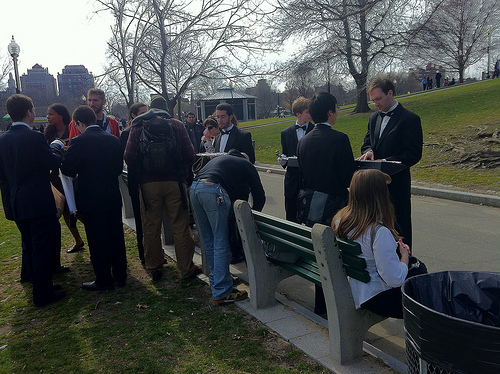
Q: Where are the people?
A: In a park.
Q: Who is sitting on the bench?
A: A woman.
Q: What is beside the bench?
A: A trash can.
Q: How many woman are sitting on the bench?
A: 1.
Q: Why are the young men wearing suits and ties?
A: For a formal event.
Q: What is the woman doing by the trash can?
A: Sitting on a bench.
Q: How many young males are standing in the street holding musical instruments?
A: 3.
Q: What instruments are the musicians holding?
A: Keyboards.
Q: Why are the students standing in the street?
A: Waiting for a competition.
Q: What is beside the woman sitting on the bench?
A: Trash can.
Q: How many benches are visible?
A: 1.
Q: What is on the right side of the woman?
A: Trash can.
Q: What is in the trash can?
A: Bag.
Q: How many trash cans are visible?
A: 1.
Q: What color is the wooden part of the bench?
A: Green.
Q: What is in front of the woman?
A: Road.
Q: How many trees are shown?
A: 4.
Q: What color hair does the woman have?
A: Brown.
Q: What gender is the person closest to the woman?
A: Male.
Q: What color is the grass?
A: Green.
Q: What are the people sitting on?
A: Bench.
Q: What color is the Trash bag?
A: Black.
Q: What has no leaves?
A: The trees.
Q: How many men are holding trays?
A: Three.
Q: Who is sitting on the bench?
A: A woman.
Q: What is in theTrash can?
A: Plastic bag.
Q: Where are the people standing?
A: In the park.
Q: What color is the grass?
A: Green.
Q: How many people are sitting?
A: One.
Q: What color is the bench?
A: Green and gray.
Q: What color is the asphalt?
A: Gray.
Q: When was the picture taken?
A: Daytime.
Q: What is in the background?
A: Buildings.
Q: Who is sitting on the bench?
A: A woman.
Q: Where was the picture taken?
A: Near street.